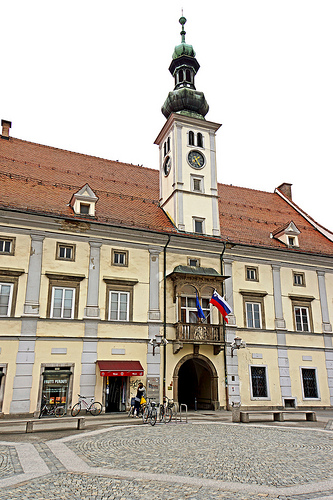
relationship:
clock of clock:
[186, 148, 207, 171] [187, 150, 206, 171]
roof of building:
[2, 158, 292, 219] [12, 92, 295, 412]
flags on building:
[187, 291, 243, 323] [12, 92, 295, 412]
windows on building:
[183, 124, 208, 158] [12, 92, 295, 412]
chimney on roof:
[0, 118, 16, 135] [2, 158, 292, 219]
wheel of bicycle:
[149, 412, 159, 424] [141, 403, 164, 428]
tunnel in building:
[176, 362, 215, 408] [12, 92, 295, 412]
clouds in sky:
[251, 48, 304, 104] [1, 5, 332, 193]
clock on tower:
[187, 150, 206, 171] [164, 30, 214, 235]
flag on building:
[214, 291, 230, 318] [12, 92, 295, 412]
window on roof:
[78, 186, 99, 209] [2, 158, 292, 219]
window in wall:
[112, 292, 126, 322] [1, 227, 324, 400]